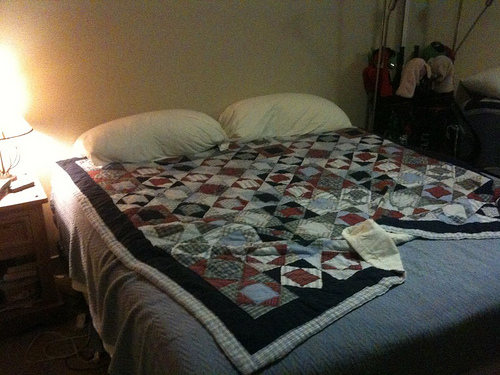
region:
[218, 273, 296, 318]
multi color quilt square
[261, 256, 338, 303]
multi color quilt square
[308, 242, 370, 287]
multi color quilt square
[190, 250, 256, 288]
multi color quilt square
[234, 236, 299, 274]
multi color quilt square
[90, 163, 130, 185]
multi color quilt square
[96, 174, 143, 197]
multi color quilt square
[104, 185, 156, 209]
multi color quilt square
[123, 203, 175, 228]
multi color quilt square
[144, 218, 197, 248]
multi color quilt square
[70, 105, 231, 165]
a white pillow on a bed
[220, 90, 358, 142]
a white pillow on a bed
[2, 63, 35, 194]
a lamp on a bed side table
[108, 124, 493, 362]
a quilt on a bed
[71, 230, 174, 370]
a blue blanket on a bed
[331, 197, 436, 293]
a crumpled up edge of a quilt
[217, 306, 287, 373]
the corner of a quilt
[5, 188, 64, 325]
a bed side end table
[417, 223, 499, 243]
the edge of a quilt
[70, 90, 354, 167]
two white pillows on a bed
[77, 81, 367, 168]
two white bed pillows on bed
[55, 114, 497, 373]
multi-color patchwork quilt lined in navy blue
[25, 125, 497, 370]
light blue blanket under quilt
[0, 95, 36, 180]
night light on night stand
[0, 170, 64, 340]
wooden night stand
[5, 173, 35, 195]
book on nightstand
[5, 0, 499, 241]
plain crema colored walls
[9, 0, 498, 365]
indoor evening bedroom scene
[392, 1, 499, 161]
mirror against wall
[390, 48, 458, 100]
white boxing gloves on display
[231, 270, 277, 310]
design on fancy quilt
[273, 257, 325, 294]
design on fancy quilt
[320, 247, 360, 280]
design on fancy quilt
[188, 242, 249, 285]
design on fancy quilt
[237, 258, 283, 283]
design on fancy quilt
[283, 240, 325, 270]
design on fancy quilt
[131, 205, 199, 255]
design on fancy quilt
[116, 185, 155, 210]
design on fancy quilt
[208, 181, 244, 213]
design on fancy quilt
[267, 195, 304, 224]
design on fancy quilt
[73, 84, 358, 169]
Two pillows are on a bed.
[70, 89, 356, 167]
Two pillows are side by side.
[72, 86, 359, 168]
The color of two pillows is white.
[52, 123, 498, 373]
A quilt is on a bed.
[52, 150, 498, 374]
A bedspread is under a quilt.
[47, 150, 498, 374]
The color of a bedspread is blue.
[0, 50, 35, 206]
A lamp is on a nightstand.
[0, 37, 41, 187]
A lamp is on.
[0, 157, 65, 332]
The color of a nightstand is brown.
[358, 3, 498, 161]
Several objects are in the background.